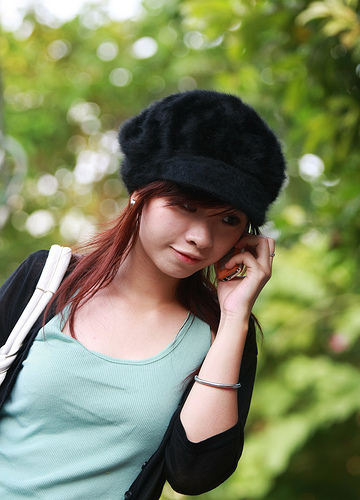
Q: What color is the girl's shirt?
A: Green.